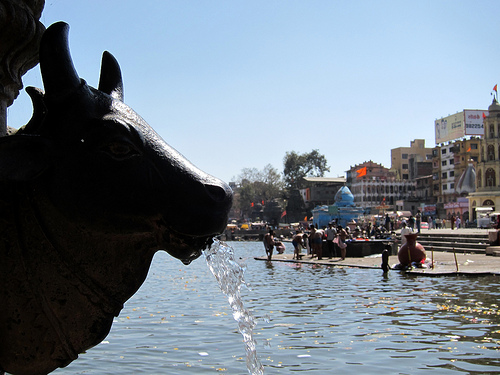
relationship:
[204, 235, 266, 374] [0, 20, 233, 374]
water spilling from statue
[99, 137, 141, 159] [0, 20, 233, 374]
eye of statue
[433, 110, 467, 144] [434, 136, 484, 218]
billboard atop building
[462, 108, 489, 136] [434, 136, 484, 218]
billboard atop building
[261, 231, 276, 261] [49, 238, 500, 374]
man near water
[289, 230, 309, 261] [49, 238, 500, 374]
person playing near water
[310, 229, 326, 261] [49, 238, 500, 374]
person playing near water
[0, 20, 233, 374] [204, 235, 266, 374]
statue spitting water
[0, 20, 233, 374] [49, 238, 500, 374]
statue near water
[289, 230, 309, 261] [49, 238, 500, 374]
person near water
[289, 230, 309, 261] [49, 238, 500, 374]
person standing near water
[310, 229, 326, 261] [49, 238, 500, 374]
person standing near water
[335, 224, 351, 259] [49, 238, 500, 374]
person standing near water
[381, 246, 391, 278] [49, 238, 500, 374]
person in water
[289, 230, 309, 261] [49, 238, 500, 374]
person at water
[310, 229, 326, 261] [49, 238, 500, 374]
person at water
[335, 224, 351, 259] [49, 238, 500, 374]
person at water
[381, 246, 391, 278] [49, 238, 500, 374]
person at water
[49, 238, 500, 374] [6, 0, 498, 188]
water reflecting sky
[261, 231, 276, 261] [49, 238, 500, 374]
man on side of water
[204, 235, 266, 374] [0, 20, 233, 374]
water coming out of statue